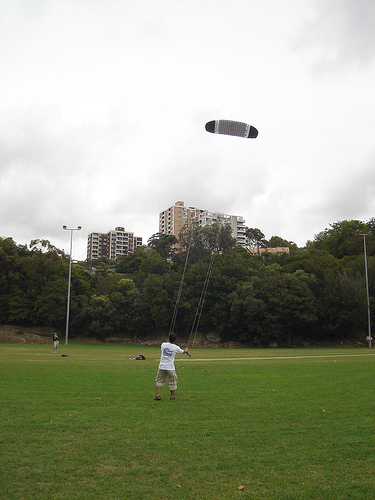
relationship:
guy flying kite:
[154, 332, 189, 400] [203, 118, 260, 138]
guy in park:
[154, 332, 189, 400] [3, 215, 371, 494]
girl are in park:
[52, 331, 60, 353] [0, 322, 373, 498]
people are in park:
[126, 353, 148, 362] [0, 322, 373, 498]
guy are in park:
[154, 332, 189, 400] [0, 322, 373, 498]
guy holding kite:
[154, 332, 189, 400] [171, 120, 245, 343]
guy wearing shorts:
[154, 332, 189, 400] [152, 368, 179, 389]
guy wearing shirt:
[154, 332, 189, 400] [158, 341, 184, 371]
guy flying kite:
[152, 331, 190, 401] [169, 99, 316, 150]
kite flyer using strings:
[155, 330, 189, 401] [168, 191, 223, 350]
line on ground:
[171, 339, 374, 370] [196, 343, 370, 407]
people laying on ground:
[127, 353, 147, 361] [3, 342, 373, 498]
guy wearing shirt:
[154, 332, 189, 400] [155, 339, 178, 371]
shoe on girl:
[53, 350, 57, 354] [52, 331, 60, 353]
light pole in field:
[62, 225, 82, 345] [0, 338, 369, 498]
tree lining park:
[4, 236, 372, 344] [8, 312, 363, 494]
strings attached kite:
[178, 152, 206, 341] [204, 115, 259, 140]